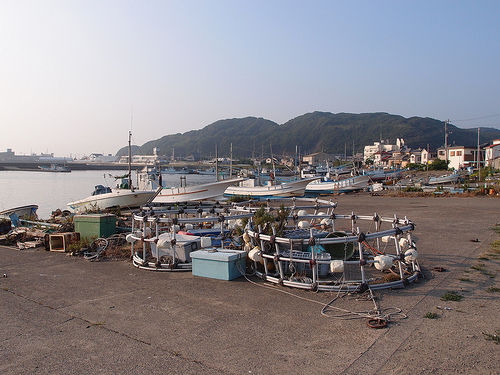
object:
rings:
[125, 197, 421, 292]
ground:
[0, 111, 500, 374]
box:
[189, 248, 247, 281]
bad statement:
[0, 0, 499, 374]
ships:
[67, 163, 459, 215]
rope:
[321, 272, 409, 322]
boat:
[108, 178, 243, 204]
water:
[0, 170, 240, 222]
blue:
[192, 257, 247, 281]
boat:
[115, 146, 159, 166]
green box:
[72, 213, 117, 241]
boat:
[66, 130, 163, 214]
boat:
[428, 170, 458, 184]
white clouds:
[0, 0, 500, 158]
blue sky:
[0, 0, 500, 159]